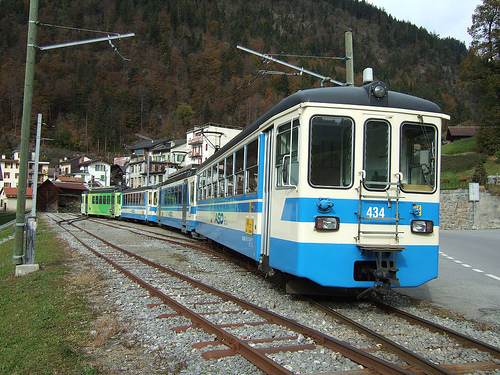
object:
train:
[77, 78, 438, 293]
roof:
[124, 134, 168, 149]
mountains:
[235, 6, 464, 106]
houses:
[79, 155, 115, 188]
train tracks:
[41, 212, 409, 373]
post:
[13, 20, 45, 276]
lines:
[442, 246, 494, 278]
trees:
[111, 70, 149, 111]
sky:
[398, 0, 461, 34]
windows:
[244, 139, 260, 194]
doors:
[255, 121, 275, 277]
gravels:
[111, 244, 209, 281]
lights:
[313, 214, 345, 234]